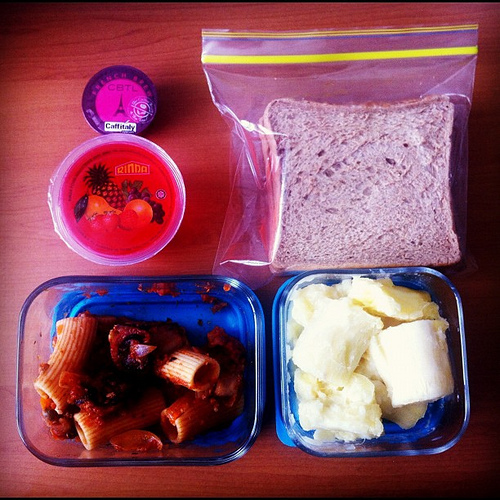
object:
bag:
[200, 21, 478, 277]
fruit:
[123, 199, 150, 231]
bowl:
[47, 133, 188, 269]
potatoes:
[370, 318, 447, 409]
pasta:
[34, 316, 247, 451]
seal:
[203, 44, 479, 65]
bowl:
[271, 270, 451, 448]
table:
[2, 4, 497, 499]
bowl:
[15, 275, 265, 466]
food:
[37, 314, 105, 409]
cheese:
[292, 303, 378, 381]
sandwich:
[259, 98, 462, 278]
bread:
[260, 96, 462, 271]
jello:
[64, 141, 177, 260]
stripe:
[203, 44, 477, 67]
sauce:
[109, 325, 169, 362]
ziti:
[166, 344, 218, 386]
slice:
[263, 95, 463, 273]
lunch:
[22, 26, 476, 467]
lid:
[266, 277, 448, 448]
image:
[83, 161, 128, 211]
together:
[27, 50, 477, 470]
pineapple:
[87, 167, 117, 209]